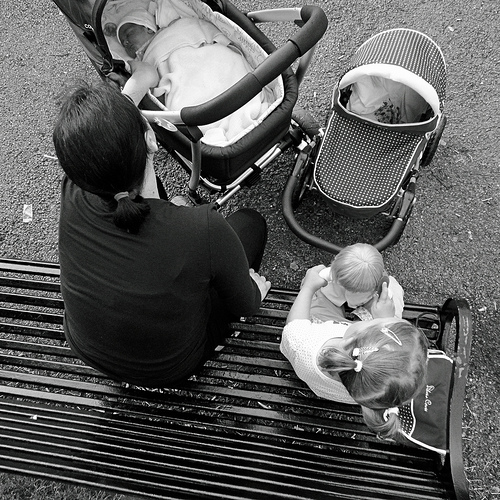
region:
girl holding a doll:
[280, 242, 426, 439]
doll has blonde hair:
[330, 240, 387, 292]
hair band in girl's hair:
[352, 358, 362, 373]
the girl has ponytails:
[320, 349, 400, 438]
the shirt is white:
[277, 319, 359, 405]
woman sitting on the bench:
[55, 86, 271, 388]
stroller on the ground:
[283, 27, 445, 254]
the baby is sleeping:
[115, 13, 272, 145]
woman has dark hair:
[51, 86, 149, 226]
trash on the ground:
[21, 202, 35, 224]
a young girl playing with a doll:
[283, 234, 434, 420]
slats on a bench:
[25, 388, 280, 483]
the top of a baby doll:
[318, 237, 407, 314]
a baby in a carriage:
[78, 9, 330, 183]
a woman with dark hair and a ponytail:
[38, 75, 158, 236]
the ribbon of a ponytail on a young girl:
[345, 346, 375, 374]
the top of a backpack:
[402, 337, 456, 458]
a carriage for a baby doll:
[308, 24, 465, 236]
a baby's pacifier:
[100, 19, 119, 42]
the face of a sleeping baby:
[116, 8, 163, 64]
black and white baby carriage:
[277, 25, 471, 260]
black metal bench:
[2, 250, 477, 499]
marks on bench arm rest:
[452, 310, 476, 381]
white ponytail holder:
[339, 350, 371, 377]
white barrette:
[373, 325, 410, 352]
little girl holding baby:
[277, 243, 437, 446]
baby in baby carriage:
[53, 2, 333, 218]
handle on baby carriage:
[127, 5, 340, 133]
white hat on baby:
[109, 5, 171, 42]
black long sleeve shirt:
[45, 175, 262, 392]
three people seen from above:
[51, 6, 431, 437]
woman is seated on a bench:
[0, 79, 472, 498]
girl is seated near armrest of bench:
[279, 261, 473, 440]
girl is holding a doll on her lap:
[279, 242, 426, 437]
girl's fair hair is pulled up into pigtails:
[318, 321, 429, 440]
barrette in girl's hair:
[380, 326, 402, 346]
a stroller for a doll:
[278, 27, 448, 254]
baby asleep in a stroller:
[48, 0, 325, 207]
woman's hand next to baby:
[115, 10, 272, 127]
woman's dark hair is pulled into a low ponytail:
[52, 77, 149, 232]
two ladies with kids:
[81, 5, 391, 442]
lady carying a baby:
[313, 268, 449, 408]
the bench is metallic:
[212, 375, 379, 491]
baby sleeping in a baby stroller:
[105, 3, 327, 154]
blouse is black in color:
[90, 239, 241, 362]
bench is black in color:
[187, 402, 320, 494]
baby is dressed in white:
[159, 36, 247, 103]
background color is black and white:
[101, 36, 498, 393]